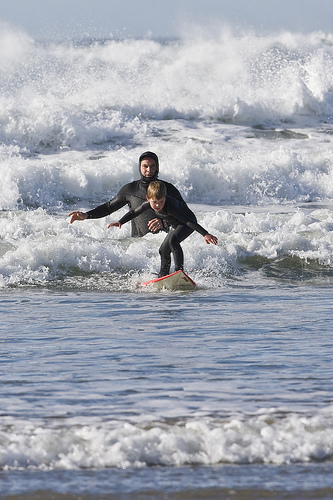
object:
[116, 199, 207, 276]
wetsuit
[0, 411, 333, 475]
foam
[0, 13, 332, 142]
waves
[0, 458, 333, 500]
shore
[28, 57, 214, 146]
foam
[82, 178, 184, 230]
wetsuit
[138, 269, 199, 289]
surfboard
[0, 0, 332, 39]
sky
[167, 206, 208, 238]
arm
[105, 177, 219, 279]
boy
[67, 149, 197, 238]
adult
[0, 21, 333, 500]
water